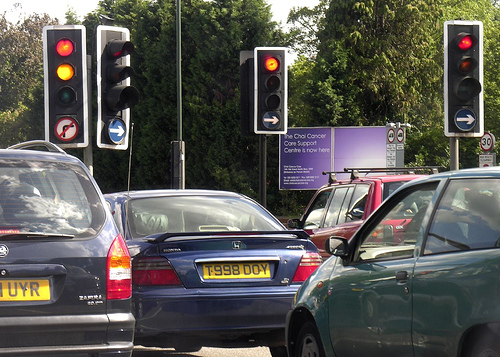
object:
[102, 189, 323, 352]
car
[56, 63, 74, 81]
signal light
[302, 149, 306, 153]
letters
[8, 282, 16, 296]
letters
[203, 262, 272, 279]
license plate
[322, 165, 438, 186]
rack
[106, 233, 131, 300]
light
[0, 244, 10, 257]
logo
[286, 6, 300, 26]
leaves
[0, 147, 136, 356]
vehicle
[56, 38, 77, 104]
traffic light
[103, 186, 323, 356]
vehicle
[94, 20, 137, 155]
traffic light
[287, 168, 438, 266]
vehicle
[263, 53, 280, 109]
traffic light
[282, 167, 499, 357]
vehicle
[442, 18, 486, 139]
traffic light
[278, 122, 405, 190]
sign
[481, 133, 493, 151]
sign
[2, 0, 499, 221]
trees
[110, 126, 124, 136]
arrow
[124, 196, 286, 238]
rear window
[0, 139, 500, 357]
traffic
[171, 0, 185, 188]
pole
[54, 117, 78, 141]
sign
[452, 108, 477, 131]
sign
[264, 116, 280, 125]
sign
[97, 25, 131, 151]
outline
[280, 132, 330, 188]
writing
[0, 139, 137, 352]
van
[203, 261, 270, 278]
writing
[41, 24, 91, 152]
traffic signal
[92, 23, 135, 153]
traffic signal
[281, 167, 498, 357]
van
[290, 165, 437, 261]
van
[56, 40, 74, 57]
light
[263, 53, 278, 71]
light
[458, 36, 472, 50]
light